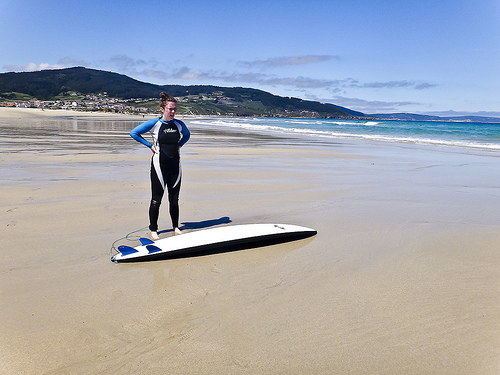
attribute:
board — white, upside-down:
[127, 219, 327, 272]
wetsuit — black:
[134, 110, 188, 225]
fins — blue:
[110, 238, 155, 264]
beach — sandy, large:
[284, 150, 458, 231]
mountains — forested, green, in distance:
[36, 65, 336, 118]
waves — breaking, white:
[259, 107, 432, 141]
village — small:
[18, 78, 139, 114]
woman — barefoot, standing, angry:
[109, 75, 199, 222]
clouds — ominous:
[152, 29, 381, 100]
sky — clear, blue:
[365, 5, 467, 96]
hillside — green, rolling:
[51, 68, 155, 95]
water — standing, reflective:
[76, 109, 133, 146]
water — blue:
[390, 123, 497, 129]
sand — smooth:
[335, 171, 490, 366]